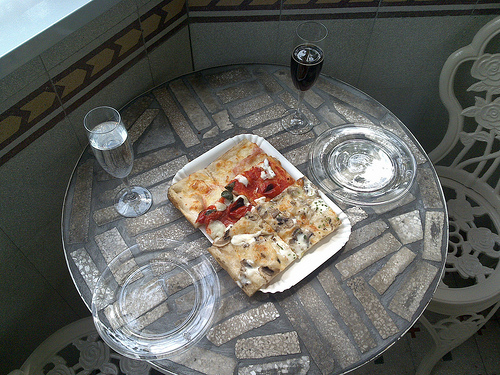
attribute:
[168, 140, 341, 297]
pizza — square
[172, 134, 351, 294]
plate — white, rectangular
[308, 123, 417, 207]
plate — transparent, clear, glass, round, empty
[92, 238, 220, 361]
plate — transparent, round, clear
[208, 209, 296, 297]
pizza — square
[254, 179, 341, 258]
pizza — square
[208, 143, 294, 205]
pizza — square, cheesy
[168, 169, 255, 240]
pizza — square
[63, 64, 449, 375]
table — round, black, stone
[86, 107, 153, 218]
glass — tall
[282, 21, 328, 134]
glass — large, half full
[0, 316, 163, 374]
chair — white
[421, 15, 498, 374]
chair — white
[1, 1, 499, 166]
border — yellow, brown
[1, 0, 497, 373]
wall — grey